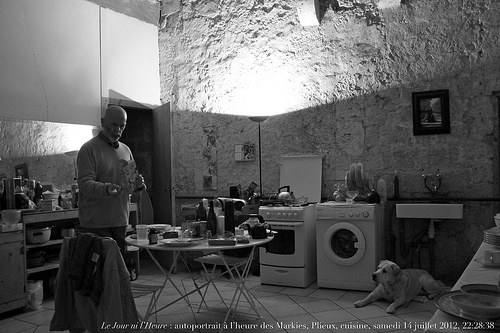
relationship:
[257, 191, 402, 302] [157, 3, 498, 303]
machines near wall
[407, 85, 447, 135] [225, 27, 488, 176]
picture on wall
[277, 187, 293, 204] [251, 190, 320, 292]
teapot on stove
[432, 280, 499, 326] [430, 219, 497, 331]
bowls on countertop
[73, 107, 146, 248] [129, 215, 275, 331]
man standing by table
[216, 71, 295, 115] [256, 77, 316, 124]
light shining off wall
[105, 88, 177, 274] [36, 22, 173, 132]
door on wall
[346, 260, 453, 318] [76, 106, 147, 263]
dog looking at man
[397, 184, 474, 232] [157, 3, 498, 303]
sink on wall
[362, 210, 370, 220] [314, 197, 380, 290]
knob on washing machine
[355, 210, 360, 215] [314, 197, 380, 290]
knob on washing machine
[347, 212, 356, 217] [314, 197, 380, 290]
knob on washing machine